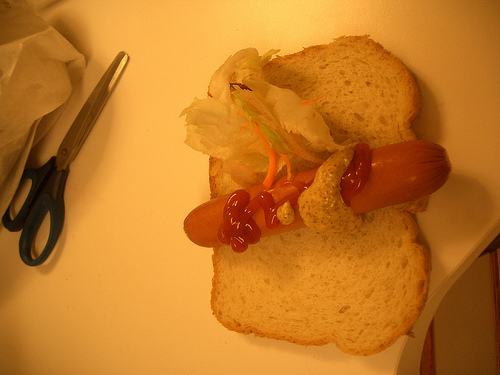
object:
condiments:
[217, 142, 383, 254]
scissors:
[0, 50, 130, 269]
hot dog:
[183, 136, 450, 253]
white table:
[2, 1, 498, 373]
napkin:
[0, 27, 87, 218]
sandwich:
[181, 34, 453, 353]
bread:
[207, 35, 432, 359]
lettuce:
[178, 45, 359, 177]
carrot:
[249, 121, 292, 189]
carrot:
[299, 96, 322, 106]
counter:
[0, 2, 493, 370]